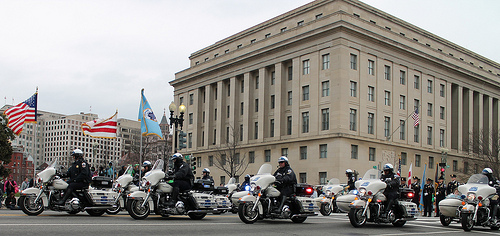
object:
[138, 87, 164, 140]
flag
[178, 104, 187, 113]
lamps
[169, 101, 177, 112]
lamps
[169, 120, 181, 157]
post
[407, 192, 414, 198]
red light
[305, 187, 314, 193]
red light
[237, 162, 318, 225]
motorcycle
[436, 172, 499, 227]
motorcycle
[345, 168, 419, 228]
motorcycle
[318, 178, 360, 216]
motorcycle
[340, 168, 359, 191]
police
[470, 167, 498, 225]
police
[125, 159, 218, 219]
motorcycle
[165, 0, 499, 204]
building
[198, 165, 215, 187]
police officer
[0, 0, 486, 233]
background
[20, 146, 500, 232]
parade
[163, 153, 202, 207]
officer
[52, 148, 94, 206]
officer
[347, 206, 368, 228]
tire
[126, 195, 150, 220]
tire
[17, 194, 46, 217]
tire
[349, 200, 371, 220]
fender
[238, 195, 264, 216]
fender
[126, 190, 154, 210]
fender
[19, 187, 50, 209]
fender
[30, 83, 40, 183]
pole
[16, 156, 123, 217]
motorcycle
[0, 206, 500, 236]
road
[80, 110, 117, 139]
flag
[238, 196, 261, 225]
wheel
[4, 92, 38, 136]
american flag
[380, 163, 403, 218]
police officer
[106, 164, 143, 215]
motorcylce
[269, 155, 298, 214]
police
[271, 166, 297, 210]
outfit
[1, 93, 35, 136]
flag